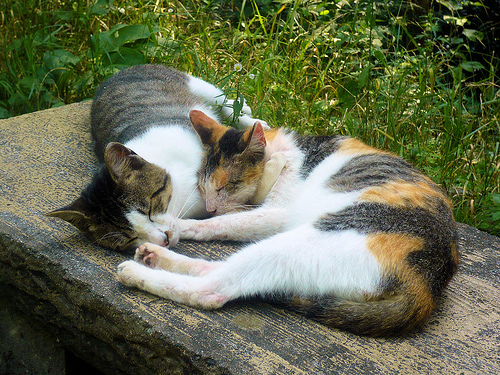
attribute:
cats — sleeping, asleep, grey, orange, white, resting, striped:
[86, 69, 457, 317]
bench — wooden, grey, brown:
[15, 129, 130, 346]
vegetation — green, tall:
[82, 14, 402, 59]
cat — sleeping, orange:
[205, 127, 452, 300]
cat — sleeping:
[94, 52, 214, 190]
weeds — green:
[262, 5, 433, 87]